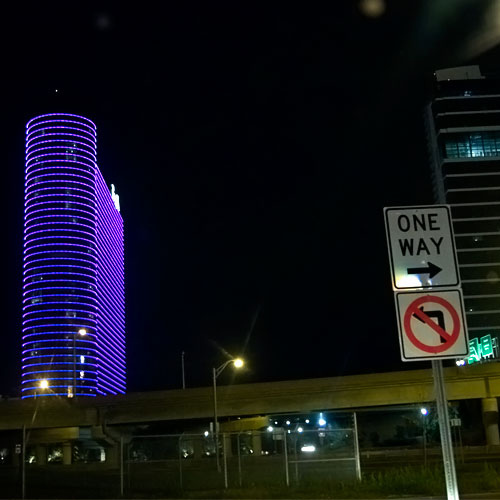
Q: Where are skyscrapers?
A: A city.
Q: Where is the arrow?
A: On sign.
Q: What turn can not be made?
A: Left turn.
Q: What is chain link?
A: Fence.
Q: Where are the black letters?
A: On the sign.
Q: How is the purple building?
A: Lit up.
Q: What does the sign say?
A: One way.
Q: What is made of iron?
A: Fence.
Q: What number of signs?
A: Two.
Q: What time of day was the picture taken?
A: At night.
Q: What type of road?
A: Expressway.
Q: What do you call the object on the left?
A: Building.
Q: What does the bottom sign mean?
A: No left turn.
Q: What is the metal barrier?
A: Fence.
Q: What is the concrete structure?
A: Overpass.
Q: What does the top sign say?
A: One way.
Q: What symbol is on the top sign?
A: Arrow.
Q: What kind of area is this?
A: Metro.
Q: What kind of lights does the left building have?
A: Neon.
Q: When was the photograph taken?
A: During the night.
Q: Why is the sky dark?
A: It is nighttime.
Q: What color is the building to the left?
A: Purple.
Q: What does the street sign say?
A: ONE WAY.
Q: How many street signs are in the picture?
A: Two.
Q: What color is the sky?
A: Black.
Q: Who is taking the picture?
A: The photographer.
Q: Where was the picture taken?
A: In the city.